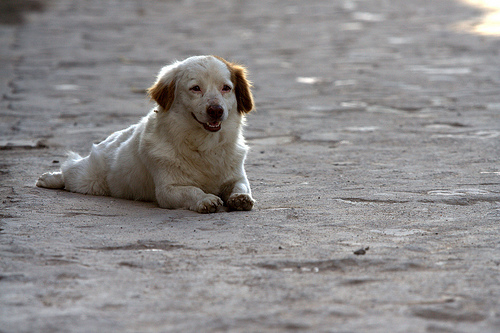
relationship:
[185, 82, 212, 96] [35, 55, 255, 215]
eye of dog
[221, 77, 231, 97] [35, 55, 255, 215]
eye of dog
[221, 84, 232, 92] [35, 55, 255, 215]
eye of dog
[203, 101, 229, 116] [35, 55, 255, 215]
nose of dog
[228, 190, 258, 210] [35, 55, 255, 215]
paw of dog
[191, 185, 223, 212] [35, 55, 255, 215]
paw of dog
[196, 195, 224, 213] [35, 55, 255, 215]
paw of dog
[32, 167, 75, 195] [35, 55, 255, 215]
back paw of dog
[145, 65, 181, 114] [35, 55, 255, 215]
ear of dog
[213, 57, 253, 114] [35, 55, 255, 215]
ear of dog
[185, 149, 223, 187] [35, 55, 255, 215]
chest of dog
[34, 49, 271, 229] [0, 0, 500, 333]
dog lying on dirt ground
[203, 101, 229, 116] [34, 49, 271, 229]
nose of dog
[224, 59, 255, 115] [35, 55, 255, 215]
ear of dog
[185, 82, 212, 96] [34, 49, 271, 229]
eye of dog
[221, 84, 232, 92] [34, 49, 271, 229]
eye of dog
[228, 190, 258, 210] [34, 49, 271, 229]
paw of dog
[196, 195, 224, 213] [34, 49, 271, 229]
paw of dog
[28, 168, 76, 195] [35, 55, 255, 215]
leg of dog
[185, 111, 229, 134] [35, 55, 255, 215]
mouth of dog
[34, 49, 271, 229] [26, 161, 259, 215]
dog with legs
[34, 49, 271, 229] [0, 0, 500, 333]
dog sitting on dirt ground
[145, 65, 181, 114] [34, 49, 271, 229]
ear of dog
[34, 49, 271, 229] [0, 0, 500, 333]
dog laying on dirt ground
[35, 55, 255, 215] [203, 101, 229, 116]
dog has nose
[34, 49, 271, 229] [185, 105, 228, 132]
dog has mouth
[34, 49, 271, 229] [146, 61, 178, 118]
dog has ear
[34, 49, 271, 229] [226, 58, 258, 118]
dog has ear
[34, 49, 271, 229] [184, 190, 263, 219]
dog has claws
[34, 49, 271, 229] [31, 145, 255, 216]
dog has legs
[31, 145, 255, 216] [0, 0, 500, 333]
legs on dirt ground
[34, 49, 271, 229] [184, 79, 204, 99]
dog has eye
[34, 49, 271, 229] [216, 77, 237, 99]
dog has eye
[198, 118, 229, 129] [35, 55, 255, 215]
teeth on dog